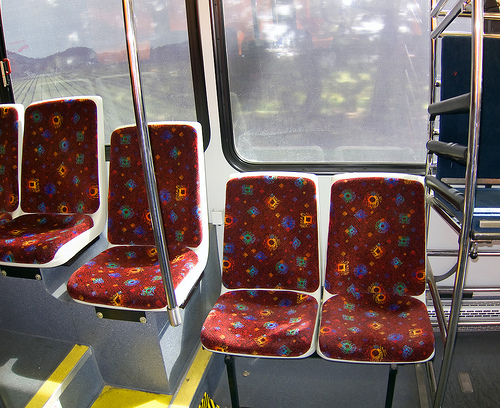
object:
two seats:
[198, 169, 322, 366]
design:
[261, 189, 283, 214]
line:
[162, 330, 219, 405]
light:
[237, 7, 443, 70]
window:
[211, 0, 444, 174]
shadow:
[9, 328, 116, 401]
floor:
[8, 315, 220, 406]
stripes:
[201, 385, 216, 407]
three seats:
[313, 158, 443, 372]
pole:
[115, 4, 193, 328]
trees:
[250, 5, 346, 123]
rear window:
[6, 2, 211, 162]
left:
[7, 5, 203, 408]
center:
[7, 14, 382, 372]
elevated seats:
[1, 77, 106, 271]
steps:
[0, 313, 102, 408]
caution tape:
[29, 335, 94, 406]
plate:
[91, 305, 147, 331]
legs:
[220, 347, 242, 408]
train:
[9, 5, 497, 400]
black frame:
[206, 2, 255, 184]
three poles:
[424, 84, 478, 120]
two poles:
[431, 0, 495, 406]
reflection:
[125, 327, 197, 384]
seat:
[66, 110, 211, 327]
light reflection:
[122, 16, 150, 135]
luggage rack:
[422, 5, 498, 398]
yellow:
[98, 390, 174, 407]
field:
[12, 9, 459, 158]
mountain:
[13, 47, 135, 82]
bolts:
[136, 315, 148, 327]